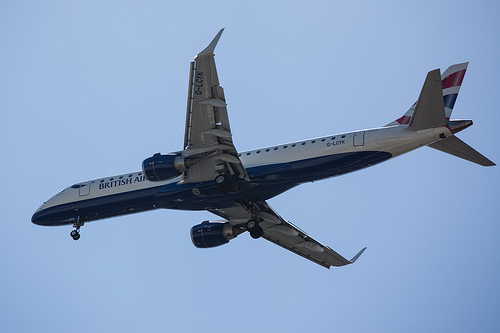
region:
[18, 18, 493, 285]
The plane is flying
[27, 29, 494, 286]
The plane is in the sky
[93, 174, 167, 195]
Blue letters on the side of the plane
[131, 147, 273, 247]
The plane has two engines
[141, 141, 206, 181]
The engine is blue and silver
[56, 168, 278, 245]
The landing gear is down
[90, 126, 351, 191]
Long row of oval windows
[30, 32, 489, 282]
The plane is blue, white and red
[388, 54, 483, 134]
Blue and red stripes on tail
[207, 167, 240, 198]
Wheel is black and grey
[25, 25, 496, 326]
british air plane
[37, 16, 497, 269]
blue and white plane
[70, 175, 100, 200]
door on air plane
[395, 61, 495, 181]
tail wings on plane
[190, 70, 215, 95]
number on plane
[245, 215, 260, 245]
right wheel on plane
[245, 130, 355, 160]
windows on air plane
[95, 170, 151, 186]
name on airplane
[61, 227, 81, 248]
front wheel on plane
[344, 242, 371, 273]
wing tip on plane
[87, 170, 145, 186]
windows on the plane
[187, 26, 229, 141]
the wing on the plane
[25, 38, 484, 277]
the plane is blue and white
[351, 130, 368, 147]
door on the plane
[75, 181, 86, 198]
a door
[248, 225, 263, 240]
wheel of the plane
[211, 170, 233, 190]
wheel of the plane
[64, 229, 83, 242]
the front wheels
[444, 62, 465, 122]
tail of the plane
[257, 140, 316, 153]
windows on the plane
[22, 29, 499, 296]
a ait plane in the air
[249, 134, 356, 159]
small round windows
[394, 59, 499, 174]
rear end of plane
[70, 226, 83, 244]
front wheels of plane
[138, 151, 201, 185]
motors on the wings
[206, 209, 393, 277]
wing of the plane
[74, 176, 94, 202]
door on the side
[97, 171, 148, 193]
whiteing on the side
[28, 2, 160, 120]
clear blue skys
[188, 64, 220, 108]
number on bottom of wing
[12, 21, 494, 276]
the plane in the air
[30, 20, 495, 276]
the plane is flying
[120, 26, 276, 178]
the wing of the plane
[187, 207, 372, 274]
the wing of the plane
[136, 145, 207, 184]
the engine under the wing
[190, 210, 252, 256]
the engine under the wing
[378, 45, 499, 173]
the tail of the plane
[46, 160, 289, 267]
the landing gear is down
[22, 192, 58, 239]
the nose of the plane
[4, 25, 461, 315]
the plane is red white and blue